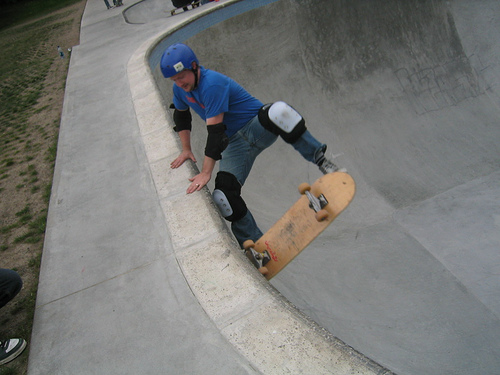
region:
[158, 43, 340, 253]
this is a man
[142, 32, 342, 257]
the man is skating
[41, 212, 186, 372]
the pavement is gray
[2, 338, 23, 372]
this is a shoe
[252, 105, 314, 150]
this is a protective knee cap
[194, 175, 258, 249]
this is a protective knee cap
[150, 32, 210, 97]
this is a blue helmet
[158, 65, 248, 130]
the t-shirt is blue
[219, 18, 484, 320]
the ramp is paved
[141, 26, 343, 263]
this is a person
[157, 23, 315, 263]
the person is doing tricks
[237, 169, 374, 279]
this is a skate board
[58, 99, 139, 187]
the pavement is gray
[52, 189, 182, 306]
the pavement is gray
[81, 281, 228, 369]
the pavement is gray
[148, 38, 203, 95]
this is a helmet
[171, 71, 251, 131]
the shirt is blue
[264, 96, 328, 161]
this is a knee cap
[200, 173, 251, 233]
this is a knee cap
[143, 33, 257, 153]
man is wearing helmet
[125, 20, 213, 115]
man is wearing helmet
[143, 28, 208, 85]
the helmet is blue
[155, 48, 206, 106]
the helmet is blue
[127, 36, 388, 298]
man skating at skating ring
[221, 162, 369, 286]
man on skate board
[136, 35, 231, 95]
man wearing blue helmet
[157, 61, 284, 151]
man wearing blue shirt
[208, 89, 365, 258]
man wearing jeans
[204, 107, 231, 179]
man wearing black elbow pads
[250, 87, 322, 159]
black and white knee pads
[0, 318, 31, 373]
black and white shoe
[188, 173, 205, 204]
man wearing wedding ring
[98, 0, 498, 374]
concrete skating ring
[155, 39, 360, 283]
a man riding a skateboard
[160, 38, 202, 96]
a man wearing a blue helmet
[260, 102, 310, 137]
a man wearing black and white knee pads